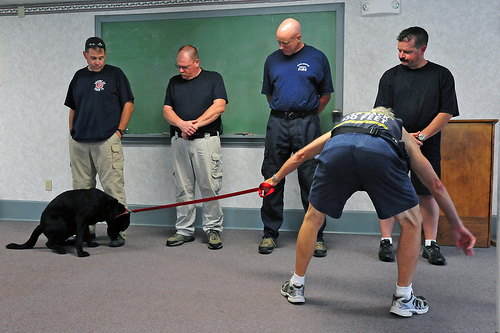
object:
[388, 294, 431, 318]
shoe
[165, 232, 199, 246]
shoe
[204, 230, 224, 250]
shoe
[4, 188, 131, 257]
dog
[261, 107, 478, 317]
man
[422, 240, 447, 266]
shoe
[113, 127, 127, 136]
watch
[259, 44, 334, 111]
tee shirt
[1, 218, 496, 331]
carpet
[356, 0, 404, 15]
light box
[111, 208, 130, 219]
collar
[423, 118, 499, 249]
podium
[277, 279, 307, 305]
shoe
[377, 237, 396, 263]
shoe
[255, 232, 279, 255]
shoe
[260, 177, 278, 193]
hand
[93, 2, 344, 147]
chalkboard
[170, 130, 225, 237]
pants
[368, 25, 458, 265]
man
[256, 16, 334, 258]
man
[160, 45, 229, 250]
man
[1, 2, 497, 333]
room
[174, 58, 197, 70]
glasses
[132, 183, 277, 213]
leash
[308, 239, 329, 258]
shoe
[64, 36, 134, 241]
man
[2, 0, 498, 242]
wall